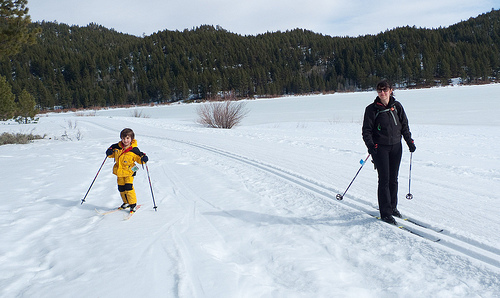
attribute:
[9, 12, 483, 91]
trees — Large amounts 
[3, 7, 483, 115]
trees — Large amounts , background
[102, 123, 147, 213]
boy — dressed , yellow , black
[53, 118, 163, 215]
boy — smiling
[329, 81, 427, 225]
woman — smiling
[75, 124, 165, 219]
boy — skiing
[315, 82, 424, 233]
woman — skiing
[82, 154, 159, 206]
pole —  child's snow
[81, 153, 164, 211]
pole —  child's snow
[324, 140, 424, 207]
pole — adult's snow 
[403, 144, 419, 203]
pole — adult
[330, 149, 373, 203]
pole — adult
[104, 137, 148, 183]
coat — yellow, black, winter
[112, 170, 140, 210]
pants — yellow, black, snow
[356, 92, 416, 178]
coat — black, winter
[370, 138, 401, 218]
pants — black, snow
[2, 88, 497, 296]
field — snow covered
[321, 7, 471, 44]
clouds — white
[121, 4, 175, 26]
clouds — white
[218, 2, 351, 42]
clouds — white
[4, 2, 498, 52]
sky — blue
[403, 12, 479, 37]
clouds — white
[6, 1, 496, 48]
sky — blue, cloudy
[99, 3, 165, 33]
clouds — white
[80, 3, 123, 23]
clouds — white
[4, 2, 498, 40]
sky — blue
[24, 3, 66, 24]
clouds — white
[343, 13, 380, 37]
clouds — white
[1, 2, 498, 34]
sky — blue